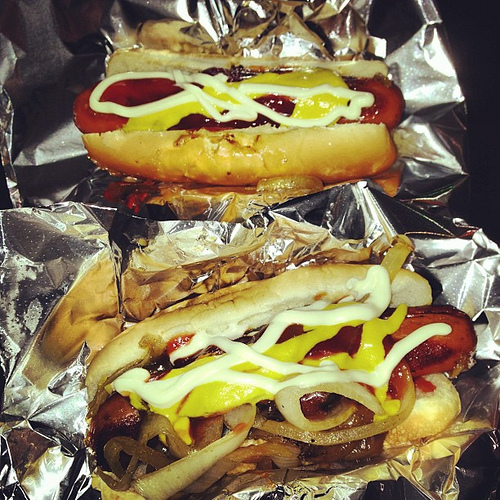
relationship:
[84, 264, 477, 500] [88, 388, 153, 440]
bun on hotdog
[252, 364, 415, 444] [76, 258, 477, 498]
onion on hotdog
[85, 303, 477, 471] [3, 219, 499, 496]
hot dog on foil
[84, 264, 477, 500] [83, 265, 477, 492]
bun on hot dog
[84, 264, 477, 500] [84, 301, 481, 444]
bun on hot dog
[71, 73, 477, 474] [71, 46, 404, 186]
hot dogs on hot dog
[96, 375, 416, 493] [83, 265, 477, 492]
onion on hot dog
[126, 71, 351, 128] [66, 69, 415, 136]
mustard on hotdog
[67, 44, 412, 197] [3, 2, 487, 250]
bun on foil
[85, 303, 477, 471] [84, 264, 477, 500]
hot dog with bun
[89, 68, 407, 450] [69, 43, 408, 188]
ketchup used on hotdog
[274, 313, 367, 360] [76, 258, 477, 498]
ketchup used on hotdog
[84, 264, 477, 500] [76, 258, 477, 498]
bun used on hotdog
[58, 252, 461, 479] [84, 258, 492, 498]
hot dog used on bun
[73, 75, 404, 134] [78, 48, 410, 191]
hot dog used on bun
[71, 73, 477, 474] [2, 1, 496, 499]
hot dogs are on foil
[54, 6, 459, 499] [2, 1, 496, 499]
hot dogs are on foil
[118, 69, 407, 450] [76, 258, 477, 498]
mustard on hotdog